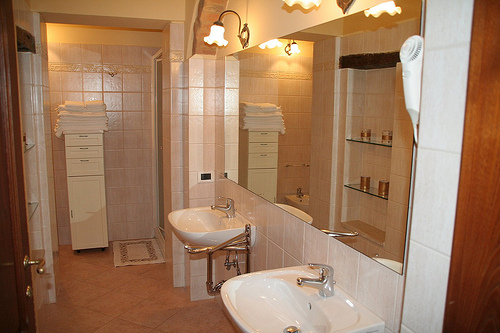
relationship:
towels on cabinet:
[53, 100, 107, 137] [64, 134, 109, 250]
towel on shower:
[64, 100, 106, 111] [150, 45, 167, 243]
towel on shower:
[56, 103, 106, 113] [150, 45, 167, 243]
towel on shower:
[57, 110, 106, 118] [150, 45, 167, 243]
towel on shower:
[61, 114, 108, 119] [150, 45, 167, 243]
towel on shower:
[58, 119, 108, 123] [150, 45, 167, 243]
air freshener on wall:
[399, 34, 423, 146] [180, 1, 472, 331]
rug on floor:
[112, 238, 167, 268] [79, 245, 151, 309]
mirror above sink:
[225, 0, 424, 274] [219, 265, 386, 332]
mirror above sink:
[225, 0, 424, 274] [166, 198, 256, 250]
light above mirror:
[200, 9, 249, 48] [213, 0, 433, 288]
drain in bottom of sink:
[282, 325, 301, 331] [219, 265, 386, 332]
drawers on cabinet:
[64, 132, 101, 177] [59, 126, 112, 252]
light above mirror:
[202, 21, 230, 48] [225, 0, 424, 274]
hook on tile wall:
[105, 69, 120, 80] [45, 43, 161, 243]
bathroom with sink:
[5, 1, 497, 326] [168, 204, 257, 251]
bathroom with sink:
[5, 1, 497, 326] [219, 265, 386, 332]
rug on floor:
[108, 233, 168, 268] [58, 243, 259, 328]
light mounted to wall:
[200, 10, 250, 52] [236, 12, 285, 52]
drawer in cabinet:
[64, 144, 103, 158] [59, 126, 112, 252]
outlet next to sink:
[197, 170, 214, 181] [166, 198, 256, 250]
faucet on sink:
[211, 196, 237, 218] [166, 198, 256, 250]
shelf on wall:
[345, 133, 391, 148] [338, 20, 411, 275]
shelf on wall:
[343, 174, 390, 201] [338, 20, 411, 275]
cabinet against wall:
[59, 126, 112, 252] [42, 43, 221, 278]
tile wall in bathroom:
[116, 71, 146, 231] [5, 1, 497, 326]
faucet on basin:
[209, 196, 236, 215] [166, 199, 258, 256]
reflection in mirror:
[339, 65, 394, 246] [225, 0, 424, 274]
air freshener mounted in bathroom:
[399, 34, 423, 146] [5, 1, 497, 326]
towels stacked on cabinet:
[53, 100, 107, 137] [59, 126, 112, 252]